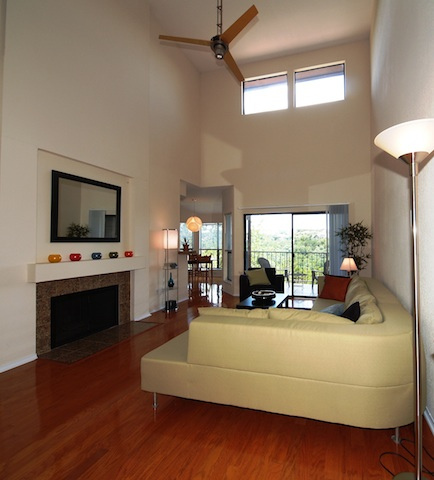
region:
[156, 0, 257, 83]
three bladed ceiling fan on high ceiling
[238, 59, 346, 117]
two second story windows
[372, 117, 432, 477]
a standing silver pole lamp with white lamp shade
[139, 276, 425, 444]
a n off white sectional living room couch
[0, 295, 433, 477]
a dark brown hard wood floor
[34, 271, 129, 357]
a brick fire place with a black screen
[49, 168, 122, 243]
a black framed mirror hanging over fire place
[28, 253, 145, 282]
a white wooden fire place mantel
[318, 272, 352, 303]
a red pillow on a white couch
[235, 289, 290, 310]
a dark brown coffee table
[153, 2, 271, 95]
a wooden ceiling fan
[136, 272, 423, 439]
a tan leather couch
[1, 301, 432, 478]
a hardwood floor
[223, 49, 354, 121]
a window near the ceiling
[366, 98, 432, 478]
a floor lamp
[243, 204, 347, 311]
a sliding glass door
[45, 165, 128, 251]
a mirror above a fireplace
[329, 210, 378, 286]
a green plant in the corner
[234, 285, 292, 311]
a dark coffe table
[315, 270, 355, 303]
an orange pillow on a coffee table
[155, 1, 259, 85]
ceiling fan with three blades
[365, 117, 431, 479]
a floor lamp turned on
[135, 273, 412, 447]
white leather sectional couch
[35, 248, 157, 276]
five glass candles on the mantle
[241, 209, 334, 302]
sliding glass doors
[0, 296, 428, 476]
shiny hard wood floor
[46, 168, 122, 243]
a black framed mirror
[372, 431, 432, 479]
black cord laying on the floor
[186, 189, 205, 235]
round lamp hanging from ceiling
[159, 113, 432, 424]
four turned on lamps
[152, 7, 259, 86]
ceiling fan attached to a white ceiling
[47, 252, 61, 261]
yellow glass candle holder on the mantle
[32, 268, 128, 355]
stone fireplace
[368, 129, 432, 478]
tall, silver floor lamp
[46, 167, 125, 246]
mirror on a white wall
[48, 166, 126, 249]
mirror with a black frame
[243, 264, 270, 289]
white throw pillow in a black chair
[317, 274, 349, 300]
red throw pillow on a cream couch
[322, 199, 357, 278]
long, blue curtain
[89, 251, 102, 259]
blue, glass candle holder on the mantle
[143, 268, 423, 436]
a large beige couch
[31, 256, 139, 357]
a fireplace with a white mantle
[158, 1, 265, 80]
a ceiling fan with three blades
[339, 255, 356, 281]
a lighted table lamp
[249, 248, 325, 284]
an exterior railing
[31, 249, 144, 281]
a mantle with five brightly colored bowls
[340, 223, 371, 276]
a large plant next to a sliding glass door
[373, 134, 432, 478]
a floor lamp with a white shade and silver pole